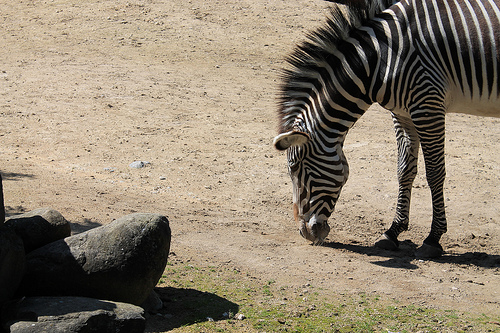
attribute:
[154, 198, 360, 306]
dirt — small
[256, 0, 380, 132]
mane — black and white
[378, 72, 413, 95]
stripes — thin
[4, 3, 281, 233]
dirt — brown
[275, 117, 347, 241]
head — bent down 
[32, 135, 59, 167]
dirt — brown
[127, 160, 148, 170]
rock — small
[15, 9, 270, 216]
dirt — brown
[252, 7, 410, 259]
zebra — black, white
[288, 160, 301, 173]
eye — black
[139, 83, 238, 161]
ground — dry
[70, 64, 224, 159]
dirt — brown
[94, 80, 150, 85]
dirt — brown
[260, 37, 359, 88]
hair — long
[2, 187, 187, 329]
rocks — large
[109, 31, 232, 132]
dirt — brown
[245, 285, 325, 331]
grass — green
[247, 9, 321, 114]
mane — black, white